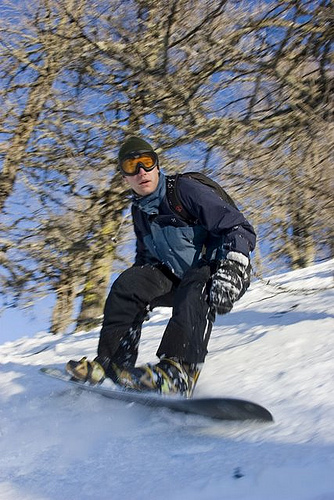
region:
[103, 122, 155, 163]
man has green cap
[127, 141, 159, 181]
black and orange goggles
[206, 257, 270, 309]
man has black gloves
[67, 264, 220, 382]
man has black pants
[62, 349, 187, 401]
black and brown boots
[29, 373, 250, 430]
man on black snowboard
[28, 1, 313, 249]
bare trees behind man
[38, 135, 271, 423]
A man snowboarding.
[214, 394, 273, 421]
Part of the snowboard.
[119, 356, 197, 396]
The man's boot.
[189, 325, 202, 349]
Part of the black pants.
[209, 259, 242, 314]
The man's black glove.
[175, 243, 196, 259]
Part of the blue jacket.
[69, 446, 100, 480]
Part of the ground.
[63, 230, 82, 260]
Part of the tree.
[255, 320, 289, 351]
White snow on the ground.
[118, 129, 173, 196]
head of a person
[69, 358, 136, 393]
feet of a person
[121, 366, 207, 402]
feet of a person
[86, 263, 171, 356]
leg of a person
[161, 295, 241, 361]
leg of a person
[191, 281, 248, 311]
hand of a person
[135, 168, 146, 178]
nose of a person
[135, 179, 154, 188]
mouth of a person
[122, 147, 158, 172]
goggle of a person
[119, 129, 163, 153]
hat of a person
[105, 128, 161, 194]
head of a person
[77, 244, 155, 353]
leg of a person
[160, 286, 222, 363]
leg of a person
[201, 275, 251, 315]
hand of a person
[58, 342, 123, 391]
feet of a person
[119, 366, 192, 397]
feet of a person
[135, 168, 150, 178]
nose of a person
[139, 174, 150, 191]
mouth of a person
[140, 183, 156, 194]
jaw of a person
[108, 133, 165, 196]
head of a person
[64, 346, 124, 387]
feet of a person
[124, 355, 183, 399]
feet of a person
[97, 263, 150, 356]
leg of a person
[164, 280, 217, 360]
leg of a person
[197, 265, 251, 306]
hand of a person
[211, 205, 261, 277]
arm of a person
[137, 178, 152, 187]
mouth of a person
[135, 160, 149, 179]
nose of a person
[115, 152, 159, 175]
Goggles on a man's face.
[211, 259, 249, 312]
Black glove on a man's hand.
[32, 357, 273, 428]
Snowboard under a man's feet.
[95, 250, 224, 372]
Black pants on a man.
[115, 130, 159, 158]
Black hat on a man's head.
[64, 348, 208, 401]
Boots on a man's feet.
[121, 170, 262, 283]
Blue jacket on a man's body.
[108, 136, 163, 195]
A man's head with googles on.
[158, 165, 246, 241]
Backpack on a snowboarder.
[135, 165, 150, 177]
Nose on a man's face.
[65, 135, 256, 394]
skier standing on a snow board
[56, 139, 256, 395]
skier wearing yellow ski goggles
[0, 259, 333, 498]
tall hill covered with snow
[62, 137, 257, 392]
skier wearing black snow pants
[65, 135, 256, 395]
skier wearing large black gloves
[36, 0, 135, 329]
tall tree growing on snow covered hill